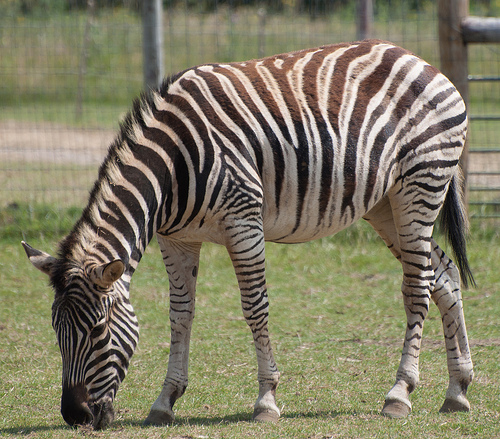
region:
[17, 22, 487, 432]
The zebra is in a fenced area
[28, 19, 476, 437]
The zebra is eating the grass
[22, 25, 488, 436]
The zebra is getting some nourishment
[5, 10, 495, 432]
The zebra belongs to a zoo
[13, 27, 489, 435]
The zebra is very relaxed and calm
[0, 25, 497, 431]
The zebra is out in the sunshine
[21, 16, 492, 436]
The zebra is awake in daytime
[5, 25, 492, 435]
The zebra is standing on grass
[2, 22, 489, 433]
The zebra is watching for danger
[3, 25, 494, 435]
The zebra is a young female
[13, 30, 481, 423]
zebra grazing in the grass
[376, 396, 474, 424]
back hooves of a zebra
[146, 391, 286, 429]
front hooves of a zebra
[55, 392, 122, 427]
nose and mouth of a zebra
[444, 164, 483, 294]
tail of a zebra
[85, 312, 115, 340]
left eye of a zebra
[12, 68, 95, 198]
fence behind the zebra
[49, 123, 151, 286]
mane on a zebra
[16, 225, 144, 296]
ears of a zebra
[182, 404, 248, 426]
shadow on the ground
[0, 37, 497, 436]
zebra eating grass on ground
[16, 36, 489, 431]
zebra has black and white stripe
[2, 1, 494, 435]
fence behind zebra eating grass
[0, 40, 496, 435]
zebra standing on grass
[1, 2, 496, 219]
pole behind fence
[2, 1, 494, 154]
grasses behind fence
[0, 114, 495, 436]
dirt in between grass on ground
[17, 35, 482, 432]
zebra has hair lined up from next to tail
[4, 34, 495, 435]
zebra standing up on grass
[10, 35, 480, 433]
zebra has a tail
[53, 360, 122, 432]
ZEBRA HAS A BLACK COLORED NOSE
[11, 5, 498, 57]
METAL FENCE IS IN THE BACKGROUND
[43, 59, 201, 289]
ZEBRA HAS A SHORT MANE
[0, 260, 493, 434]
GROUND CONSIST OF GRASS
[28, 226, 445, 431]
GRASS IS GREEN IN COLOR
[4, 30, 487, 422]
ZEBRA IS BLACK AND WHITE IN COLOR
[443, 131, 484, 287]
ZEBRA HAS A BLACK TAIL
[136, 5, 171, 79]
METAL POLES ARE IN THE BACKGROUND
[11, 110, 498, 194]
A DIRT ROAD IS IN THE BACKGROUND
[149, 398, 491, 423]
ZEBRA HAS BROWN HOOVES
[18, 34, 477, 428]
Zebra grazing in enclosure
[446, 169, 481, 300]
Black haired tail on zebra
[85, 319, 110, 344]
Black eye of zebra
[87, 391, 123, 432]
Zebra mouth grazing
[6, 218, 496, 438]
Grass covered zebra enclosure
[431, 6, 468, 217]
Wooden fence post of enclosure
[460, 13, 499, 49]
Wooden gate rail top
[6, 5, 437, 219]
Wire metal fence of enclosure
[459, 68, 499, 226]
Metal rails on gate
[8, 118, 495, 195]
Dirt road beyond fence line